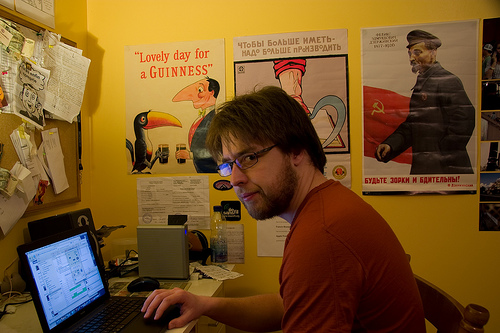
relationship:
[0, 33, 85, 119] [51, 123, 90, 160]
papers attached to cork board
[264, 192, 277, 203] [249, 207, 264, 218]
beard attached to chin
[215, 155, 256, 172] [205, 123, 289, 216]
eyeglasses attached to face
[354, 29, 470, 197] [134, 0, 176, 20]
poster attached to wall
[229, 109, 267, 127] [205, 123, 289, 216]
hair attached to face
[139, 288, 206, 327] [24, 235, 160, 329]
hand on laptop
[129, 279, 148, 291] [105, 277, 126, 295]
mouse on top of pad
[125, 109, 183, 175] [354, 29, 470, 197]
toucan on poster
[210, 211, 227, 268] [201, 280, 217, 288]
bottle on top of desk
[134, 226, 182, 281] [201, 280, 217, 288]
modem on top of desk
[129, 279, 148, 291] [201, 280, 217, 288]
mouse on top of desk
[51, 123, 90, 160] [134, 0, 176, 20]
cork board attached to wall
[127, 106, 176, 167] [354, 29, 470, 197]
toucan on poster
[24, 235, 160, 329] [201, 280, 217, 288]
laptop on top of desk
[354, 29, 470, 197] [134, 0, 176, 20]
poster on wall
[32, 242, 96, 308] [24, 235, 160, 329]
monitor of laptop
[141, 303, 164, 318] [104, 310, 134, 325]
fingers on top of keyboard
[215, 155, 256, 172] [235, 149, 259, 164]
eyeglasses on eyes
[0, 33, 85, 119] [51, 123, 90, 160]
papers on cork board